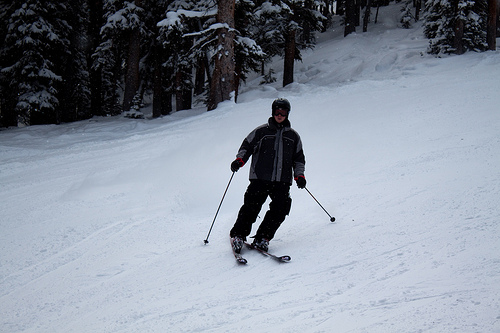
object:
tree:
[152, 1, 172, 114]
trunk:
[283, 20, 294, 83]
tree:
[207, 0, 234, 109]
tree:
[177, 0, 193, 111]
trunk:
[91, 6, 101, 115]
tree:
[55, 4, 82, 122]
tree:
[1, 6, 21, 125]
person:
[231, 98, 305, 238]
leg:
[229, 185, 268, 238]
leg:
[255, 194, 291, 238]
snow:
[0, 35, 499, 333]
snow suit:
[229, 123, 304, 238]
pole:
[205, 172, 235, 241]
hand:
[231, 158, 245, 172]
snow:
[158, 10, 215, 27]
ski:
[229, 237, 247, 264]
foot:
[231, 237, 243, 253]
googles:
[272, 109, 287, 116]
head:
[272, 98, 290, 122]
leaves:
[94, 9, 179, 37]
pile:
[283, 82, 308, 94]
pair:
[231, 237, 291, 264]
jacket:
[237, 118, 304, 181]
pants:
[229, 183, 291, 239]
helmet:
[272, 98, 290, 110]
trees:
[266, 6, 315, 86]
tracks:
[325, 288, 473, 317]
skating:
[204, 99, 335, 263]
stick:
[304, 187, 334, 218]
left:
[1, 1, 267, 332]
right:
[268, 1, 498, 332]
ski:
[244, 241, 291, 262]